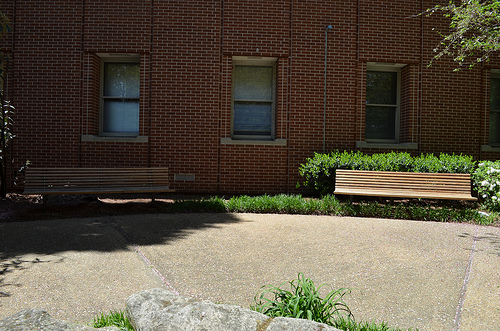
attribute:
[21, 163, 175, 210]
bench — wood, wooden, brown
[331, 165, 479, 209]
bench — brown, wood, wooden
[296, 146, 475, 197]
bushes — green, lush, leafy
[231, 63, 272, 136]
window — middle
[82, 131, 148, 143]
window sill — concrete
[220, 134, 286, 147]
window sill — concrete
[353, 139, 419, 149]
window sill — concrete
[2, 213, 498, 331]
walkway — cement, paved, large, concrete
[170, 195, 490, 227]
grass — green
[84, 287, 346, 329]
rock — large, grey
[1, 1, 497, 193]
building — brick, large, red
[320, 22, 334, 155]
conduit — metal, grey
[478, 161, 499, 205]
flowers — white